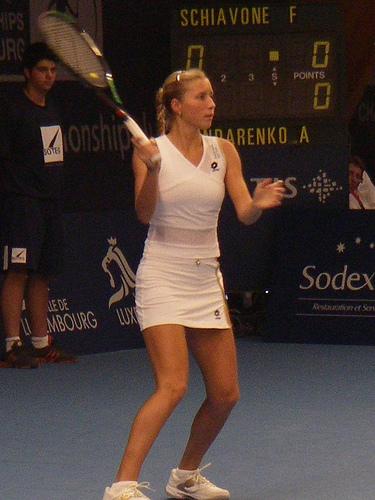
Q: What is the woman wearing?
A: A shirt and skirt.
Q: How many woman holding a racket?
A: One.